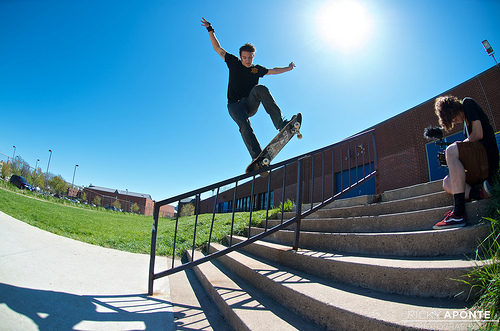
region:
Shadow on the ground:
[23, 295, 64, 311]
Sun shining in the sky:
[323, 5, 366, 45]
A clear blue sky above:
[58, 29, 102, 54]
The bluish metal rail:
[153, 204, 235, 248]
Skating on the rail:
[248, 164, 265, 171]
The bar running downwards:
[152, 207, 155, 268]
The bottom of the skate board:
[275, 140, 282, 148]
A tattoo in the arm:
[220, 52, 222, 54]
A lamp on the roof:
[481, 38, 493, 51]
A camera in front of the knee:
[438, 150, 445, 163]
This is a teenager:
[175, 30, 437, 283]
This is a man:
[200, 0, 430, 285]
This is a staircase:
[145, 237, 322, 306]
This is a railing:
[131, 142, 405, 251]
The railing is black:
[115, 182, 452, 291]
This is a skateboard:
[242, 123, 330, 190]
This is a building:
[15, 157, 212, 272]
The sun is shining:
[285, 10, 492, 111]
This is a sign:
[336, 129, 393, 197]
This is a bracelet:
[186, 20, 231, 43]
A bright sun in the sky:
[308, 0, 374, 56]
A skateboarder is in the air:
[198, 15, 307, 178]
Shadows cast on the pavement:
[1, 279, 178, 329]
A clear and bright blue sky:
[1, 0, 499, 194]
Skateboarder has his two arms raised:
[200, 12, 298, 79]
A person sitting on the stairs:
[421, 93, 499, 230]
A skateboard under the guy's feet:
[244, 112, 303, 180]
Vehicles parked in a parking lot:
[8, 165, 126, 216]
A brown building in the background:
[84, 182, 176, 221]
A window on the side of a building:
[330, 161, 379, 197]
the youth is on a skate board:
[183, 12, 326, 177]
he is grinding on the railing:
[183, 14, 336, 180]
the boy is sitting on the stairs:
[410, 76, 496, 238]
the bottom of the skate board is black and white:
[248, 107, 319, 165]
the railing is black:
[144, 122, 405, 290]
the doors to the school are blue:
[331, 165, 383, 196]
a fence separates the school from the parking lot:
[1, 154, 148, 216]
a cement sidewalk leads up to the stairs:
[0, 211, 173, 330]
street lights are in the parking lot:
[36, 144, 58, 196]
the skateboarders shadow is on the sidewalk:
[1, 277, 186, 329]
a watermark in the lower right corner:
[400, 293, 499, 329]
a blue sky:
[1, 0, 498, 202]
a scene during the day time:
[0, 3, 497, 324]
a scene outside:
[5, 3, 498, 327]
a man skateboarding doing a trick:
[192, 5, 312, 180]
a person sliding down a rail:
[144, 122, 384, 297]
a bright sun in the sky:
[292, 0, 396, 65]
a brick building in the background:
[187, 63, 497, 217]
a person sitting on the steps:
[398, 78, 498, 248]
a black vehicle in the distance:
[4, 168, 43, 198]